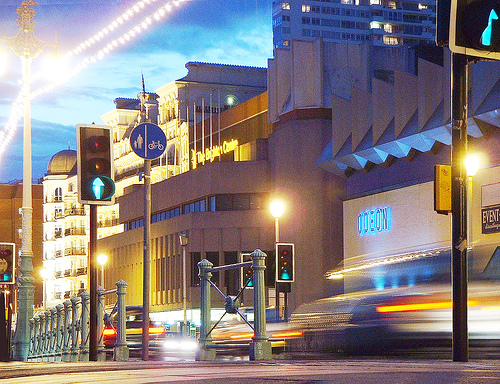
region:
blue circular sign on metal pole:
[132, 71, 177, 359]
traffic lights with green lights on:
[205, 221, 312, 315]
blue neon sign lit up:
[344, 200, 416, 247]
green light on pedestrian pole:
[450, 14, 497, 359]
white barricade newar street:
[152, 232, 287, 380]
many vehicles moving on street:
[28, 287, 498, 374]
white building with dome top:
[51, 131, 113, 349]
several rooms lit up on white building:
[277, 5, 438, 67]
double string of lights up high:
[21, 1, 198, 181]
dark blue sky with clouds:
[10, 2, 262, 149]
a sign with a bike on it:
[102, 63, 222, 220]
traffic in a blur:
[60, 253, 499, 353]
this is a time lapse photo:
[168, 247, 480, 327]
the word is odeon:
[347, 189, 432, 235]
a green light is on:
[68, 180, 179, 243]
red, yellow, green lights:
[44, 92, 134, 285]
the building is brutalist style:
[185, 152, 277, 276]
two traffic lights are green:
[216, 225, 320, 307]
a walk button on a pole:
[412, 131, 494, 241]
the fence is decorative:
[183, 250, 290, 361]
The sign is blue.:
[121, 119, 171, 165]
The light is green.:
[72, 117, 127, 220]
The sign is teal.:
[335, 199, 412, 238]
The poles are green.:
[178, 253, 288, 361]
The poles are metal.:
[177, 251, 287, 358]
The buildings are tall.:
[161, 67, 496, 342]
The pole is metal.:
[438, 29, 495, 361]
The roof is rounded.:
[33, 140, 82, 195]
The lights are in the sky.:
[13, 8, 183, 95]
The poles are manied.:
[18, 267, 150, 359]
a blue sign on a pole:
[125, 116, 169, 161]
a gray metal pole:
[136, 158, 154, 363]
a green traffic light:
[278, 267, 297, 282]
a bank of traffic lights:
[271, 235, 298, 286]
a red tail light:
[145, 320, 167, 340]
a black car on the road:
[94, 298, 166, 360]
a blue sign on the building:
[349, 199, 397, 245]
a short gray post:
[241, 244, 273, 366]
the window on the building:
[231, 187, 251, 212]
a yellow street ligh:
[264, 188, 294, 220]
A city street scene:
[11, 31, 491, 358]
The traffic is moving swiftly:
[274, 291, 498, 358]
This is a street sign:
[129, 117, 169, 358]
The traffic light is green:
[273, 241, 298, 284]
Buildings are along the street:
[168, 65, 443, 239]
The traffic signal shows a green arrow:
[76, 125, 116, 205]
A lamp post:
[11, 2, 54, 353]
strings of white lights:
[51, 23, 152, 68]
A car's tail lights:
[103, 325, 165, 340]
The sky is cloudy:
[167, 17, 268, 62]